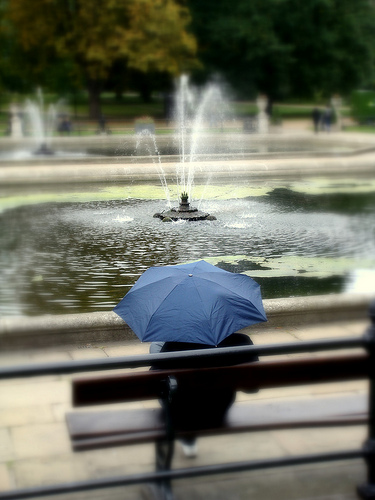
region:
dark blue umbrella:
[113, 256, 267, 347]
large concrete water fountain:
[1, 152, 373, 378]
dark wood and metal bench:
[65, 351, 371, 498]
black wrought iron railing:
[0, 311, 374, 498]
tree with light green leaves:
[0, 0, 204, 123]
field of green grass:
[1, 89, 373, 117]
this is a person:
[126, 225, 284, 461]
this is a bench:
[40, 308, 373, 458]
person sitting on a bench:
[75, 240, 272, 472]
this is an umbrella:
[108, 249, 275, 353]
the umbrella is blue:
[108, 246, 270, 349]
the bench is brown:
[62, 331, 373, 462]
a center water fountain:
[8, 48, 368, 346]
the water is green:
[19, 153, 370, 325]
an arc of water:
[121, 66, 257, 217]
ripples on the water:
[17, 158, 373, 309]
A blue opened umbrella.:
[112, 259, 267, 348]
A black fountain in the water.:
[153, 190, 215, 223]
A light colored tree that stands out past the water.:
[1, 0, 205, 118]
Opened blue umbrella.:
[112, 257, 268, 348]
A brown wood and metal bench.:
[62, 354, 373, 494]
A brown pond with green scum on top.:
[2, 174, 374, 313]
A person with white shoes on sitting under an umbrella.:
[147, 333, 260, 456]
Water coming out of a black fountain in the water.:
[131, 70, 229, 222]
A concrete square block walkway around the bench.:
[0, 326, 373, 497]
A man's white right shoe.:
[176, 438, 199, 456]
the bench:
[73, 405, 122, 435]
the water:
[177, 228, 226, 250]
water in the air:
[155, 136, 207, 190]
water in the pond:
[270, 214, 323, 246]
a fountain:
[134, 129, 218, 219]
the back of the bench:
[277, 360, 333, 379]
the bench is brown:
[281, 356, 323, 376]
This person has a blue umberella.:
[99, 252, 252, 437]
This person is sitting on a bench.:
[120, 256, 291, 485]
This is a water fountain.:
[111, 75, 274, 256]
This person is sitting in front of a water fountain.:
[126, 104, 278, 475]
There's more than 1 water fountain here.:
[15, 86, 274, 235]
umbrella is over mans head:
[112, 260, 266, 346]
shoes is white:
[176, 440, 194, 457]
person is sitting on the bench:
[150, 332, 264, 498]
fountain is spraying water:
[154, 191, 216, 225]